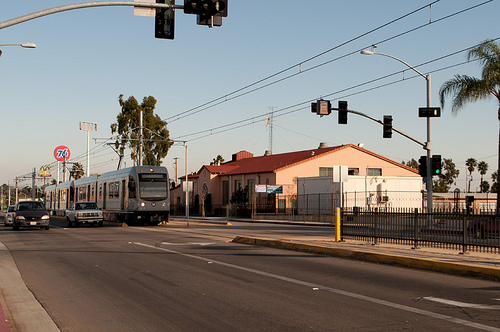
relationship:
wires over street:
[190, 48, 334, 172] [142, 199, 277, 327]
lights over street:
[276, 88, 425, 148] [142, 199, 277, 327]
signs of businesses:
[247, 145, 292, 202] [185, 135, 300, 215]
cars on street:
[13, 198, 53, 233] [142, 199, 277, 327]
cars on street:
[3, 175, 84, 245] [142, 199, 277, 327]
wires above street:
[190, 48, 334, 172] [142, 199, 277, 327]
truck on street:
[66, 183, 109, 242] [142, 199, 277, 327]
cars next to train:
[13, 198, 53, 233] [109, 140, 178, 212]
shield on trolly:
[137, 170, 171, 202] [84, 169, 186, 233]